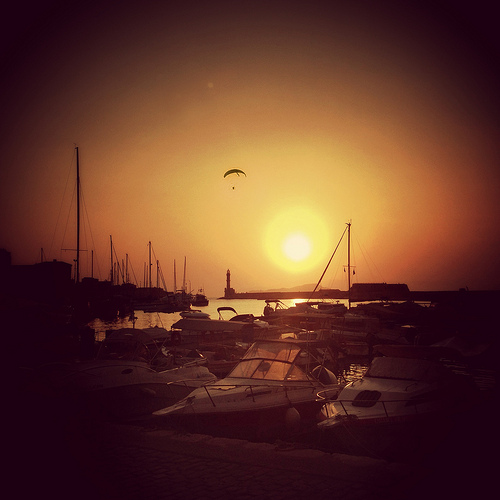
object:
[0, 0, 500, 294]
sky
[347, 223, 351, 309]
pole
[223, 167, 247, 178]
bird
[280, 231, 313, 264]
sun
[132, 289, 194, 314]
boat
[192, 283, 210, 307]
boat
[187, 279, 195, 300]
silhouette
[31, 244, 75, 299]
silhouette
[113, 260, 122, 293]
silhouette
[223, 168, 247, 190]
para sail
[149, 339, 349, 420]
boat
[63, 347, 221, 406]
boat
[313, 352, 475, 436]
boat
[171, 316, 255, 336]
boat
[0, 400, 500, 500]
dock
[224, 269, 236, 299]
building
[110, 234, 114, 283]
mast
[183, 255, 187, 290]
mast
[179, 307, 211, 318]
boat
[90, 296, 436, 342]
water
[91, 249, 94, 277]
mast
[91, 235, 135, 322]
ship